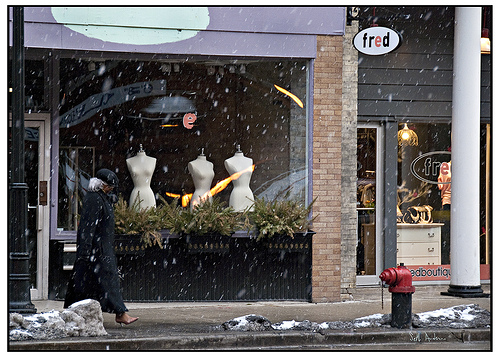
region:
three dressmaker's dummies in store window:
[123, 147, 258, 215]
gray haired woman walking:
[61, 167, 142, 329]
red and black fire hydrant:
[378, 260, 420, 328]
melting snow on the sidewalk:
[11, 298, 496, 355]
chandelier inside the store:
[393, 122, 421, 147]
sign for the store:
[351, 24, 402, 57]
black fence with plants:
[117, 202, 317, 302]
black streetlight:
[1, 0, 38, 315]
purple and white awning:
[5, 7, 347, 59]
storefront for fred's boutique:
[8, 4, 498, 292]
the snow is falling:
[18, 14, 478, 348]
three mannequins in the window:
[119, 142, 279, 230]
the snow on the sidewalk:
[24, 298, 496, 328]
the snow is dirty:
[16, 300, 496, 332]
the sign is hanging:
[342, 25, 404, 75]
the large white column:
[443, 6, 492, 296]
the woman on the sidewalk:
[69, 166, 149, 329]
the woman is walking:
[73, 164, 157, 335]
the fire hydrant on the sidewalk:
[372, 258, 424, 325]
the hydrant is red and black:
[367, 260, 426, 322]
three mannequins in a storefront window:
[119, 133, 261, 227]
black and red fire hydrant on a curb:
[371, 255, 428, 334]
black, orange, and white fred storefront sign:
[348, 17, 422, 72]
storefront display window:
[54, 57, 304, 230]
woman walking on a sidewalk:
[65, 147, 152, 336]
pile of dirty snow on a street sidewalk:
[11, 290, 113, 337]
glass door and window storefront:
[347, 100, 471, 278]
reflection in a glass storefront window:
[64, 62, 262, 142]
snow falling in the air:
[182, 49, 319, 169]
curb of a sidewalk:
[143, 315, 483, 347]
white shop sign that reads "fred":
[352, 25, 401, 54]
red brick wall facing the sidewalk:
[315, 35, 340, 300]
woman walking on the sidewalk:
[75, 167, 122, 299]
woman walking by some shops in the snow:
[71, 168, 123, 300]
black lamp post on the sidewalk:
[10, 6, 32, 311]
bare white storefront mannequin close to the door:
[125, 142, 156, 208]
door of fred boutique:
[357, 120, 382, 267]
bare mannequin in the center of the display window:
[187, 148, 213, 204]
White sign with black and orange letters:
[350, 23, 407, 57]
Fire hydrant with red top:
[377, 260, 417, 331]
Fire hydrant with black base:
[378, 260, 416, 330]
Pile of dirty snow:
[10, 295, 116, 342]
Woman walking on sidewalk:
[64, 165, 148, 331]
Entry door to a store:
[352, 119, 387, 291]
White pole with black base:
[442, 5, 488, 300]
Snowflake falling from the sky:
[92, 61, 107, 76]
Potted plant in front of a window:
[244, 184, 320, 248]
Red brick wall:
[315, 36, 340, 298]